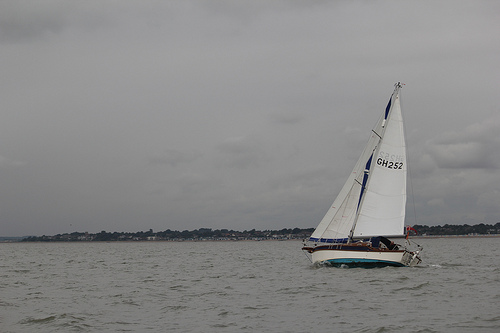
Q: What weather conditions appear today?
A: It is cloudy.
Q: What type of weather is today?
A: It is cloudy.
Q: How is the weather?
A: It is cloudy.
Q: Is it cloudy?
A: Yes, it is cloudy.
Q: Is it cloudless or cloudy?
A: It is cloudy.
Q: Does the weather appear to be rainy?
A: No, it is cloudy.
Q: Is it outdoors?
A: Yes, it is outdoors.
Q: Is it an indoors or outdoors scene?
A: It is outdoors.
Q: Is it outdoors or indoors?
A: It is outdoors.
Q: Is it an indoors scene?
A: No, it is outdoors.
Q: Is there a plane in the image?
A: No, there are no airplanes.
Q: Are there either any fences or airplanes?
A: No, there are no airplanes or fences.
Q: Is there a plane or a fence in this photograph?
A: No, there are no airplanes or fences.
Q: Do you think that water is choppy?
A: Yes, the water is choppy.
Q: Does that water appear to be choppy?
A: Yes, the water is choppy.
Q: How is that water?
A: The water is choppy.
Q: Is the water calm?
A: No, the water is choppy.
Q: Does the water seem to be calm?
A: No, the water is choppy.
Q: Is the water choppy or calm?
A: The water is choppy.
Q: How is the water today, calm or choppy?
A: The water is choppy.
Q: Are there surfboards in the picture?
A: No, there are no surfboards.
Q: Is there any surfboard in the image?
A: No, there are no surfboards.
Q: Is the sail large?
A: Yes, the sail is large.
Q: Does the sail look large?
A: Yes, the sail is large.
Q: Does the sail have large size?
A: Yes, the sail is large.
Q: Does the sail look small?
A: No, the sail is large.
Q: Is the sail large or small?
A: The sail is large.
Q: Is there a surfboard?
A: No, there are no surfboards.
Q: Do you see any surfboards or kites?
A: No, there are no surfboards or kites.